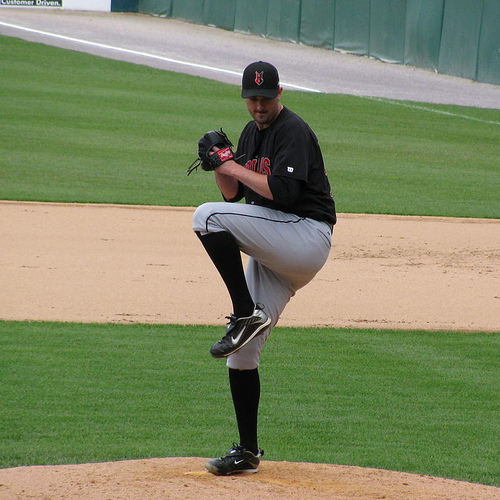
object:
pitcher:
[187, 60, 338, 483]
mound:
[0, 448, 493, 497]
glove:
[193, 128, 237, 174]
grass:
[0, 35, 500, 213]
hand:
[196, 131, 252, 196]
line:
[84, 39, 211, 72]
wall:
[97, 0, 500, 83]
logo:
[224, 147, 287, 183]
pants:
[179, 197, 333, 369]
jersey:
[218, 84, 340, 225]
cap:
[239, 60, 280, 99]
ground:
[0, 5, 500, 327]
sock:
[198, 226, 262, 326]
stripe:
[183, 203, 308, 237]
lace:
[333, 315, 405, 327]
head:
[240, 57, 283, 124]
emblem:
[287, 166, 295, 173]